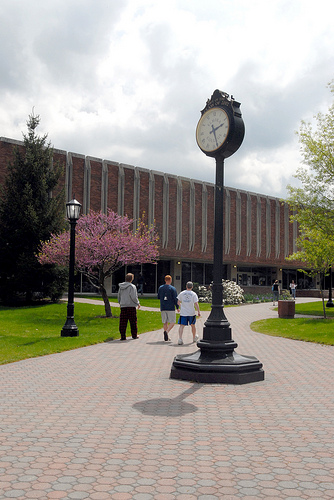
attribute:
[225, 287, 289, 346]
walkways — red, blue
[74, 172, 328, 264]
building — big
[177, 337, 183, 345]
sneaker — white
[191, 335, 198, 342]
sneaker — white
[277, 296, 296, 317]
trash can — octogonal 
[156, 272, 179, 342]
boy — red-headed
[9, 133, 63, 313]
tree — green, large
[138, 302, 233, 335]
shorts — gray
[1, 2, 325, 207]
sky — cloudy, blue-grey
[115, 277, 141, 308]
hoodie — gray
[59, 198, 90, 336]
pole — tall, black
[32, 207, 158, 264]
blossoms — pink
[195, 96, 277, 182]
clock — tall, black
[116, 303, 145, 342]
pants — black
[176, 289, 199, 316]
shirt — white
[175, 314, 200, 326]
shorts — blue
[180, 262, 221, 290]
windows — large, dark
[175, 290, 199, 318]
t-shirt — white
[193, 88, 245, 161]
clock — black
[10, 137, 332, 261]
wall — wide, brick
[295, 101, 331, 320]
green tree — large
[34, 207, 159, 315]
tree — small, slanted, large, purple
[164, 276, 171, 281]
hair — red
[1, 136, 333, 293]
building — college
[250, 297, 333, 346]
grass — green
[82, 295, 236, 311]
grass — green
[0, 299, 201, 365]
grass — green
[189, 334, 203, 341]
shoe — white, tennis shoe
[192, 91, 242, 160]
clock — large, tower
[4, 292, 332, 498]
pavers — pale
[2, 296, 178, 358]
grass — green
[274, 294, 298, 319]
receptacle — large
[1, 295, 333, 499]
campus — college